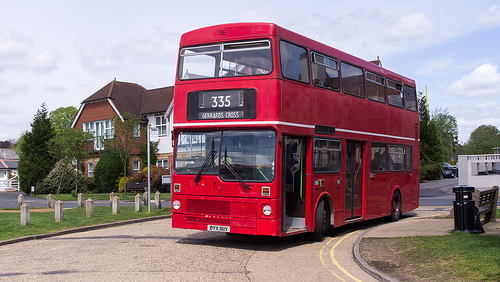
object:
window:
[279, 39, 311, 85]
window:
[310, 50, 340, 91]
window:
[340, 61, 366, 98]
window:
[386, 78, 404, 108]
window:
[404, 85, 417, 112]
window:
[313, 138, 343, 174]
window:
[370, 142, 388, 172]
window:
[388, 144, 406, 172]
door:
[280, 132, 309, 235]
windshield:
[174, 129, 277, 182]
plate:
[207, 225, 230, 233]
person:
[376, 154, 386, 170]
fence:
[17, 191, 161, 226]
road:
[0, 178, 457, 282]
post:
[54, 200, 63, 222]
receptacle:
[452, 185, 486, 235]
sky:
[0, 0, 500, 146]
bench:
[471, 185, 499, 226]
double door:
[345, 139, 365, 222]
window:
[87, 162, 97, 177]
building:
[69, 77, 207, 178]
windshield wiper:
[222, 160, 251, 189]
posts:
[20, 203, 31, 226]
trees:
[13, 101, 58, 195]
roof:
[80, 77, 174, 120]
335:
[212, 95, 232, 107]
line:
[318, 229, 361, 282]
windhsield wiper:
[194, 151, 218, 183]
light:
[263, 205, 272, 216]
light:
[173, 200, 181, 210]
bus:
[171, 22, 421, 242]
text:
[202, 111, 240, 119]